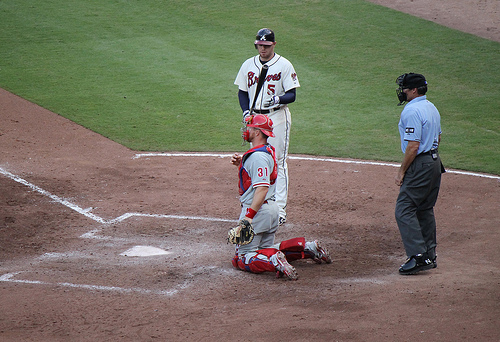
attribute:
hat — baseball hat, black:
[253, 26, 277, 46]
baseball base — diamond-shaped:
[0, 210, 262, 298]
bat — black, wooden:
[233, 49, 295, 121]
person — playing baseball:
[224, 21, 301, 106]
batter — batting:
[236, 29, 298, 225]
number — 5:
[267, 80, 277, 99]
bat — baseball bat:
[251, 58, 298, 107]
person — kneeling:
[229, 112, 330, 279]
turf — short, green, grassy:
[2, 1, 484, 178]